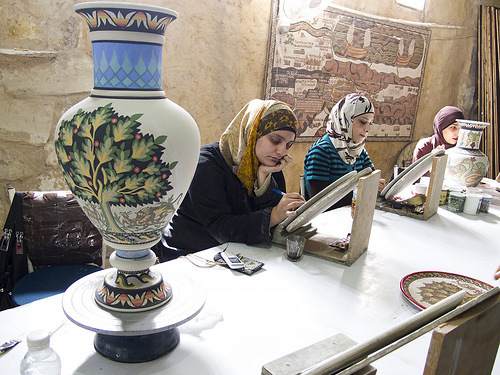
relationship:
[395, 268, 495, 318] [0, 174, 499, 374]
plate on table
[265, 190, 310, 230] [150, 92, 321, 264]
hand of woman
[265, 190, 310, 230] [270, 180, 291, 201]
hand holding art instrument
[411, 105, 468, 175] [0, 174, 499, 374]
woman at table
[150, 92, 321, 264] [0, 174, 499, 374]
woman at table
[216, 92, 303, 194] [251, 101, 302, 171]
hijab on head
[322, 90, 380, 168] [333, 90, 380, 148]
hijab around head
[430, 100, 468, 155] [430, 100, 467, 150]
hijab around head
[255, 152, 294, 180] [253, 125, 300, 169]
hand on face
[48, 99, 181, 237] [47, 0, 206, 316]
tree drawing on vase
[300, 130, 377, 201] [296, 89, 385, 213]
shirt on woman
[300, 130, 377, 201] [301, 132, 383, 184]
shirt has stripes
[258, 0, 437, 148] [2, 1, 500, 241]
art on wall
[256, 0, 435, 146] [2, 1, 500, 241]
decoration on wall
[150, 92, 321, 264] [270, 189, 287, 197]
woman using art instrument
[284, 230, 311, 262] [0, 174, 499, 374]
glass on table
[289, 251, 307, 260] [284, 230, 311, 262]
liquid in glass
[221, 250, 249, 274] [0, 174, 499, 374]
cellphone on table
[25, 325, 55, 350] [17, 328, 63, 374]
cap on water bottle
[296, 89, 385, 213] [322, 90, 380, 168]
woman wearing hijab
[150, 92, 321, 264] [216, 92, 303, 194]
woman wearing hijab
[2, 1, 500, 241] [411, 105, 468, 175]
wall behind woman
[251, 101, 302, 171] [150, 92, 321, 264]
head of woman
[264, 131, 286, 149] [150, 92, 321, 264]
eye of woman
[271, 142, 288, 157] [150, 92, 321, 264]
nose of woman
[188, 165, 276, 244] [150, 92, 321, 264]
arm of woman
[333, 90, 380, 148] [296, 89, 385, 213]
head of woman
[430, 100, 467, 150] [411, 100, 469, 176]
head of woman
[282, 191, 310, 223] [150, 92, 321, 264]
fingers of woman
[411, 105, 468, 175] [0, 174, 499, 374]
woman sitting at table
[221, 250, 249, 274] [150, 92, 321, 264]
cellphone beside woman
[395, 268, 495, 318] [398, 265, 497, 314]
plate has trim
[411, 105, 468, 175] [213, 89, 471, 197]
woman wearing hijabs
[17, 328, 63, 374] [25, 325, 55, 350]
water bottle with cap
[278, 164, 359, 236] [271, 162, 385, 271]
plate on wooden easel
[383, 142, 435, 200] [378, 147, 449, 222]
plate on wooden easel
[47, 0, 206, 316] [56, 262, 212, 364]
vase on display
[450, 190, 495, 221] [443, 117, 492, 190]
cups near vase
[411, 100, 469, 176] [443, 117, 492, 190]
woman working on vase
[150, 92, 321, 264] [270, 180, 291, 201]
woman holding art instrument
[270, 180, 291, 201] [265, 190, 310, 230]
art instrument in hand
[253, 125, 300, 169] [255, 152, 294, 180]
face on hand